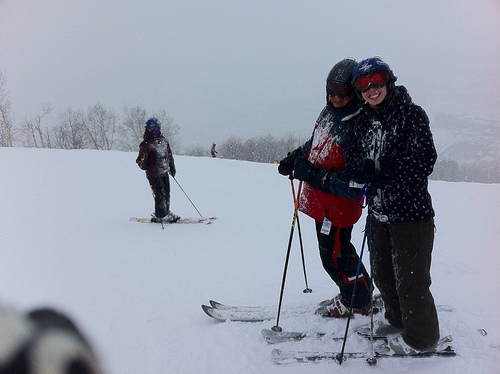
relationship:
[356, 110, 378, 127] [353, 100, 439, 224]
dot on coat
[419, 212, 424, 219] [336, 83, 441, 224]
white dot on coat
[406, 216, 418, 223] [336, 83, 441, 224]
white dot on coat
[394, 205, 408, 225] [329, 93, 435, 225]
dot on coat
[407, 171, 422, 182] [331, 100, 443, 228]
dot on coat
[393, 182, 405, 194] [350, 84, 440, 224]
white dot on coat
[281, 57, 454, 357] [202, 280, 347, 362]
people on skis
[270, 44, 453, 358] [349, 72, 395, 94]
people wears goggles